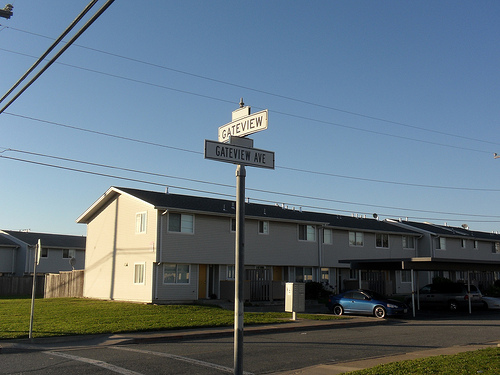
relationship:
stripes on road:
[48, 339, 256, 375] [1, 320, 498, 373]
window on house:
[136, 213, 149, 287] [82, 195, 499, 323]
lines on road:
[50, 346, 218, 373] [1, 320, 498, 373]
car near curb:
[327, 285, 404, 314] [356, 317, 388, 325]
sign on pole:
[205, 141, 276, 170] [230, 168, 243, 374]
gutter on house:
[156, 207, 333, 232] [82, 195, 499, 323]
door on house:
[201, 265, 211, 300] [82, 195, 499, 323]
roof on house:
[114, 187, 409, 231] [82, 195, 499, 323]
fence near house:
[4, 270, 83, 300] [82, 195, 499, 323]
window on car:
[349, 292, 368, 301] [327, 285, 404, 314]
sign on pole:
[33, 241, 44, 271] [29, 244, 34, 346]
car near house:
[327, 285, 404, 314] [82, 195, 499, 323]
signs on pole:
[202, 98, 275, 171] [230, 168, 243, 374]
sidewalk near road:
[275, 340, 497, 374] [1, 320, 498, 373]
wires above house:
[1, 18, 492, 218] [82, 195, 499, 323]